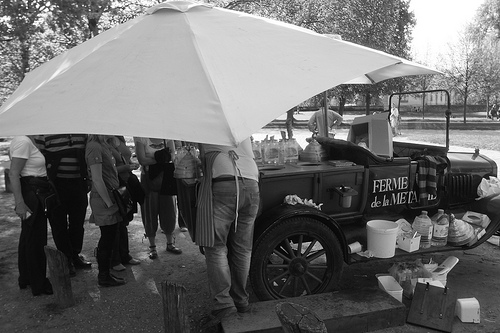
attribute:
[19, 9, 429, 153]
umbrella — large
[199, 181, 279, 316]
jeans — blue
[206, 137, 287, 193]
shirt — white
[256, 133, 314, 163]
bottles — small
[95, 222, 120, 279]
pants — black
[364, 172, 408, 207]
name — white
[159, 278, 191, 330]
post — wooden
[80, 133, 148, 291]
dress — gray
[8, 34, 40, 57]
leaves — thin